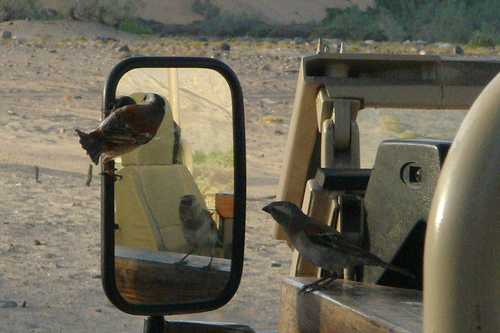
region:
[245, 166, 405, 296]
Small bird on right of mirror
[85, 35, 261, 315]
rear view mirror with bird on it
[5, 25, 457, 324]
Dirt ground behind mirror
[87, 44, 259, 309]
Black frame around mirror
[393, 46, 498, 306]
Gray metal curved rail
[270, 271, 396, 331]
Wooden box under bird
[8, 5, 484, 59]
Plants growing on ground in background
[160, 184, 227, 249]
Reflection of bird in mirror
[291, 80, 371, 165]
Bending hinge above bird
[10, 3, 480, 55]
Slope in background beyond bushes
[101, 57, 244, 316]
side view mirror of vehicle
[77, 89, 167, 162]
bird looking in mirror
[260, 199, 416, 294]
bird standing on metal surface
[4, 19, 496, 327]
sandy surface of ground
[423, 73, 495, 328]
curved tan metal surface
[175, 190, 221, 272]
reflection of bird in mirror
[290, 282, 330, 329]
shadow of bird under feet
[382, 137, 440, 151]
light reflection on edge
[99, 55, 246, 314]
black frame around mirror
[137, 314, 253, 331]
arm of mirror stand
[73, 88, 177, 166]
a bird is hanging on to a review mirror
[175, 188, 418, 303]
a bird by the mirror can also be seen in the reflection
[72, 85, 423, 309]
the two birds are looking at the mirror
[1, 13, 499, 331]
there is a lot of dirt and sand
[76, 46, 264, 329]
a review mirror on a vehicle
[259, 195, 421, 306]
the bird has many earth tone colors on it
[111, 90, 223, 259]
the seat can be seen in the review mirror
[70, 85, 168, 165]
the birds back has dark red stripes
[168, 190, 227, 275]
the front of this bird is gray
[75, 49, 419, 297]
two birds looking in the mirror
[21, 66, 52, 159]
this is the ground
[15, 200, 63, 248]
the ground is sandy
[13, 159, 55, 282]
the sand is white in color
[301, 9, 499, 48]
these are some trees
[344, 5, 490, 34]
the trees are tall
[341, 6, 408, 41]
the leaves are green in color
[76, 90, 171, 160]
this is a bird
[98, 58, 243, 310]
this is a sidemirror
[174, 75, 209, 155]
the mirror is clean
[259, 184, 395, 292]
the bird is on the car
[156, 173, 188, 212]
part of a mirror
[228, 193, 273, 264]
edge of a mirror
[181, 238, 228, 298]
part of a mirror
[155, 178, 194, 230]
part of a mirror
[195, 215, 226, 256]
part of a mirror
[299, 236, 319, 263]
part of a chest